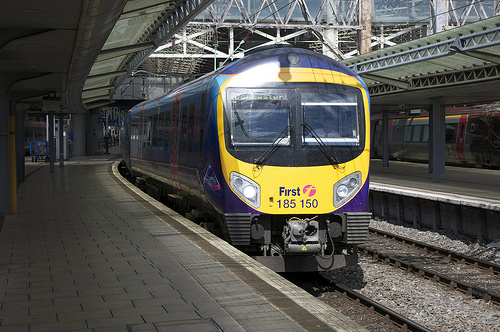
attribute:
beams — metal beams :
[142, 1, 499, 64]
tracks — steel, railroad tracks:
[390, 229, 460, 329]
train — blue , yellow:
[126, 15, 376, 283]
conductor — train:
[308, 111, 342, 136]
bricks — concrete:
[0, 211, 235, 328]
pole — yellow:
[5, 112, 17, 223]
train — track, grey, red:
[362, 95, 498, 172]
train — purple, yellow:
[120, 39, 383, 271]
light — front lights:
[227, 169, 265, 214]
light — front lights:
[325, 169, 373, 211]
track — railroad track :
[376, 278, 482, 328]